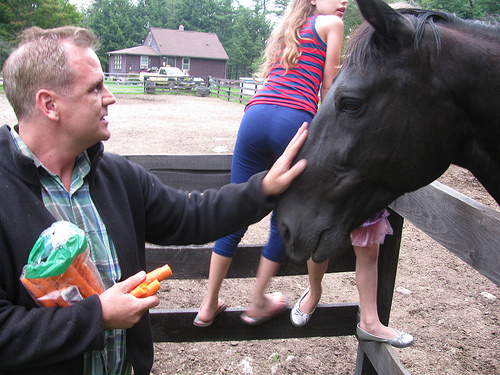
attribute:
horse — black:
[260, 1, 500, 264]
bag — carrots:
[17, 216, 114, 315]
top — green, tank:
[14, 219, 90, 285]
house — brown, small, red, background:
[103, 19, 234, 87]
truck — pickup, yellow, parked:
[137, 63, 192, 93]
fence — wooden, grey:
[1, 70, 263, 107]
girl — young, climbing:
[193, 2, 350, 330]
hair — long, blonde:
[247, 2, 312, 85]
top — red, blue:
[238, 10, 329, 127]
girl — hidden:
[290, 187, 416, 349]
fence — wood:
[1, 143, 500, 374]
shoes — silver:
[356, 321, 417, 351]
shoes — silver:
[287, 280, 324, 330]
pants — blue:
[210, 104, 317, 270]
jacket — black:
[3, 119, 277, 374]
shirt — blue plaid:
[9, 119, 139, 374]